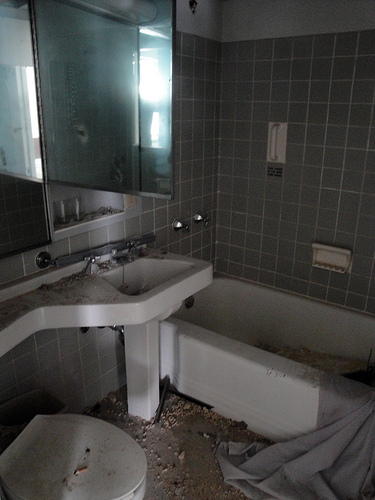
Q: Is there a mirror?
A: Yes, there is a mirror.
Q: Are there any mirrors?
A: Yes, there is a mirror.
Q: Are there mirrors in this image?
A: Yes, there is a mirror.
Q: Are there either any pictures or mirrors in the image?
A: Yes, there is a mirror.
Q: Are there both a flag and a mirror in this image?
A: No, there is a mirror but no flags.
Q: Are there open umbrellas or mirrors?
A: Yes, there is an open mirror.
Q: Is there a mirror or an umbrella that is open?
A: Yes, the mirror is open.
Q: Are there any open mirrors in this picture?
A: Yes, there is an open mirror.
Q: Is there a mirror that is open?
A: Yes, there is a mirror that is open.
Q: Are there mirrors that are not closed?
A: Yes, there is a open mirror.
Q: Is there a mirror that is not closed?
A: Yes, there is a open mirror.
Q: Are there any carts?
A: No, there are no carts.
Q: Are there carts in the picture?
A: No, there are no carts.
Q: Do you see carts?
A: No, there are no carts.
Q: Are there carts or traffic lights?
A: No, there are no carts or traffic lights.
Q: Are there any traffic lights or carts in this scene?
A: No, there are no carts or traffic lights.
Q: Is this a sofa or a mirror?
A: This is a mirror.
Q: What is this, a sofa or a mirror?
A: This is a mirror.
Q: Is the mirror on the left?
A: Yes, the mirror is on the left of the image.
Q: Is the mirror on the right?
A: No, the mirror is on the left of the image.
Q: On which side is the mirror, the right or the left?
A: The mirror is on the left of the image.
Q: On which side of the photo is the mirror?
A: The mirror is on the left of the image.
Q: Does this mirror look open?
A: Yes, the mirror is open.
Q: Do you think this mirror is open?
A: Yes, the mirror is open.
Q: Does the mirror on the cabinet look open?
A: Yes, the mirror is open.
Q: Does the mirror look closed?
A: No, the mirror is open.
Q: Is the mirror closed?
A: No, the mirror is open.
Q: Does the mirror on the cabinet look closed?
A: No, the mirror is open.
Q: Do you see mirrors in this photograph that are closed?
A: No, there is a mirror but it is open.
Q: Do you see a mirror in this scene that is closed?
A: No, there is a mirror but it is open.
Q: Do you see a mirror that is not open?
A: No, there is a mirror but it is open.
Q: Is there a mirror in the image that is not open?
A: No, there is a mirror but it is open.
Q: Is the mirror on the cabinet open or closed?
A: The mirror is open.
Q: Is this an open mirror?
A: Yes, this is an open mirror.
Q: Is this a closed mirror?
A: No, this is an open mirror.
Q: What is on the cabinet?
A: The mirror is on the cabinet.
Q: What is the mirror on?
A: The mirror is on the cabinet.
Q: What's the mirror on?
A: The mirror is on the cabinet.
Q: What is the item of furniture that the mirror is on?
A: The piece of furniture is a cabinet.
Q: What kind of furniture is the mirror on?
A: The mirror is on the cabinet.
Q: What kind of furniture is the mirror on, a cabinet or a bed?
A: The mirror is on a cabinet.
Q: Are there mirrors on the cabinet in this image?
A: Yes, there is a mirror on the cabinet.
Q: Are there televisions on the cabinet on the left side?
A: No, there is a mirror on the cabinet.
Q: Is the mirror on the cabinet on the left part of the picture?
A: Yes, the mirror is on the cabinet.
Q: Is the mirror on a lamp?
A: No, the mirror is on the cabinet.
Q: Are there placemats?
A: No, there are no placemats.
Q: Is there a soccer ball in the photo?
A: No, there are no soccer balls.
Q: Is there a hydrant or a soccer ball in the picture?
A: No, there are no soccer balls or fire hydrants.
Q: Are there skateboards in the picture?
A: No, there are no skateboards.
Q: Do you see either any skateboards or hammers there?
A: No, there are no skateboards or hammers.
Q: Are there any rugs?
A: No, there are no rugs.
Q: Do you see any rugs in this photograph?
A: No, there are no rugs.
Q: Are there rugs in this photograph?
A: No, there are no rugs.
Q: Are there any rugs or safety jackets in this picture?
A: No, there are no rugs or safety jackets.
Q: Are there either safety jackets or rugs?
A: No, there are no rugs or safety jackets.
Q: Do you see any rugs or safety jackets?
A: No, there are no rugs or safety jackets.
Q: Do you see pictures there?
A: No, there are no pictures.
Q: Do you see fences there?
A: No, there are no fences.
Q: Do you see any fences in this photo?
A: No, there are no fences.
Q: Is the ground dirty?
A: Yes, the ground is dirty.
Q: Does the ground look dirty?
A: Yes, the ground is dirty.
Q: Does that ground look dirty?
A: Yes, the ground is dirty.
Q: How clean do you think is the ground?
A: The ground is dirty.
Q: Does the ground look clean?
A: No, the ground is dirty.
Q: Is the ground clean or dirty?
A: The ground is dirty.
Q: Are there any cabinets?
A: Yes, there is a cabinet.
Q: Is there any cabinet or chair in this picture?
A: Yes, there is a cabinet.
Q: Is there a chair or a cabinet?
A: Yes, there is a cabinet.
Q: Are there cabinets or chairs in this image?
A: Yes, there is a cabinet.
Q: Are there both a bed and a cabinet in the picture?
A: No, there is a cabinet but no beds.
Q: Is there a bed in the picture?
A: No, there are no beds.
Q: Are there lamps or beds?
A: No, there are no beds or lamps.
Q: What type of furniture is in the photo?
A: The furniture is a cabinet.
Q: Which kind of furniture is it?
A: The piece of furniture is a cabinet.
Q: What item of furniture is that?
A: This is a cabinet.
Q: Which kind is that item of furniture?
A: This is a cabinet.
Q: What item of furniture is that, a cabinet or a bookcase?
A: This is a cabinet.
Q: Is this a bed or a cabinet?
A: This is a cabinet.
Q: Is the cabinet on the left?
A: Yes, the cabinet is on the left of the image.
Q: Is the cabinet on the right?
A: No, the cabinet is on the left of the image.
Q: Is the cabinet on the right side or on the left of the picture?
A: The cabinet is on the left of the image.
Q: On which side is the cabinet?
A: The cabinet is on the left of the image.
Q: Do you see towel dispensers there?
A: No, there are no towel dispensers.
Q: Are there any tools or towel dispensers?
A: No, there are no towel dispensers or tools.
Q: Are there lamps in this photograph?
A: No, there are no lamps.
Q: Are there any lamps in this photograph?
A: No, there are no lamps.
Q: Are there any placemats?
A: No, there are no placemats.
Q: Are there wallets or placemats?
A: No, there are no placemats or wallets.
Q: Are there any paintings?
A: No, there are no paintings.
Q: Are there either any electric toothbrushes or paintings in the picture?
A: No, there are no paintings or electric toothbrushes.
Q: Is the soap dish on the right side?
A: Yes, the soap dish is on the right of the image.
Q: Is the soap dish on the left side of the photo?
A: No, the soap dish is on the right of the image.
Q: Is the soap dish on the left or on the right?
A: The soap dish is on the right of the image.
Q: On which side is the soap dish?
A: The soap dish is on the right of the image.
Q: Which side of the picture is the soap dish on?
A: The soap dish is on the right of the image.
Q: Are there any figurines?
A: No, there are no figurines.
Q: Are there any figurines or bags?
A: No, there are no figurines or bags.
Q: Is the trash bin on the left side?
A: Yes, the trash bin is on the left of the image.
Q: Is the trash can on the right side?
A: No, the trash can is on the left of the image.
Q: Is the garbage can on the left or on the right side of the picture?
A: The garbage can is on the left of the image.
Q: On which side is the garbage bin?
A: The garbage bin is on the left of the image.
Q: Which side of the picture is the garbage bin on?
A: The garbage bin is on the left of the image.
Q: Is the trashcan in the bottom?
A: Yes, the trashcan is in the bottom of the image.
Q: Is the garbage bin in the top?
A: No, the garbage bin is in the bottom of the image.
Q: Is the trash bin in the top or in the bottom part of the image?
A: The trash bin is in the bottom of the image.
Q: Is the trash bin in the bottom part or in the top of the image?
A: The trash bin is in the bottom of the image.